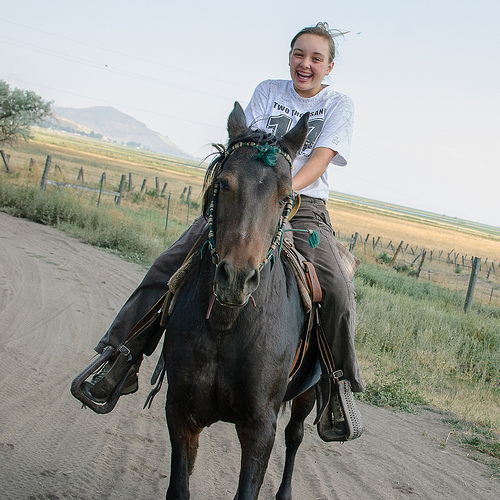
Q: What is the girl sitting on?
A: A horse.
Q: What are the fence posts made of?
A: Wood.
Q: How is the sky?
A: Hazy.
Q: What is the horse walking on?
A: A dirt road.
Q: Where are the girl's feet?
A: In the stirrups./.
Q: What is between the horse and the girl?
A: A saddle.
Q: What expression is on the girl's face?
A: A smile.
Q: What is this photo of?
A: A road.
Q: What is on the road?
A: A woman.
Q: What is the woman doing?
A: Laughing.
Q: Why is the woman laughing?
A: She is having fun.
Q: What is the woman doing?
A: Riding a horse.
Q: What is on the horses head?
A: A beaded chain.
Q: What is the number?
A: The number fourteen.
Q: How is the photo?
A: Clear.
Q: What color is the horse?
A: Black.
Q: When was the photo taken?
A: Daytime.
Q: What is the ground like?
A: Sandy.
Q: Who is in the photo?
A: A lady.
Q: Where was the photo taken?
A: On a country road.